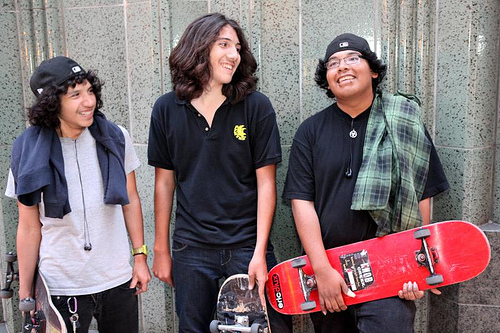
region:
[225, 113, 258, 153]
yellow logo stitched on front of shirt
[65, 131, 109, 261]
black ear buds hanging from around persons neck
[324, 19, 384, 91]
black caseball hat turned around backwards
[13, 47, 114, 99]
black caseball hat worn backwards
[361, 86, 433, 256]
gren and blue plaid shirt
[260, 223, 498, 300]
red skateboard with rubber wheels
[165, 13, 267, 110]
teenage boys with shoulder length hair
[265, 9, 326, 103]
gray and black speckled wall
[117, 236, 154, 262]
boys wide band watch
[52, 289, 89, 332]
car keys on hook attached to boys jeans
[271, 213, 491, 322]
red skateboard in his hands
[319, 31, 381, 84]
teen weaing black cap backwards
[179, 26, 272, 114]
teen with long brown hair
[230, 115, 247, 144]
yellow logo on black shirt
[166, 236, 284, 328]
dark wash denim jeans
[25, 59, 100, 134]
teen wearing cap backwards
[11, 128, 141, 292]
teen wearing white tshirt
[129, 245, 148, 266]
teen wearing yellow wrist watch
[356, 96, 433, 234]
teen with green and black shirt over shoulder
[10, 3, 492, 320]
marble wall with shiny finish behind the boys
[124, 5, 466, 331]
2 guys in black shirt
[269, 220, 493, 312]
A red skateboard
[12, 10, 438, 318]
Three boys holding skateboards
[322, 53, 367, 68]
A pair of glasses on a boy's face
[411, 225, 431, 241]
The wheel of a skateboard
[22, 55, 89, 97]
A backwards hat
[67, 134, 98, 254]
A pair of earbuds dangling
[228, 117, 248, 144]
A yellow logo on a black shirt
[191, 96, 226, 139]
An unbuttoned collar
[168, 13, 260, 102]
A boy with shoulder length hair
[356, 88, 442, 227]
A plaid shirt draped over a shoulder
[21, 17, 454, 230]
Three boys are standing.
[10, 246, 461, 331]
Boys are holding skateboard.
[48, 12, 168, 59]
Wall is grey color.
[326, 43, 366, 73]
Boy is wearing glass.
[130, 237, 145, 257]
Boy is wearing watch in left hand.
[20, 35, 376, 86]
Cap is black color.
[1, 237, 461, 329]
Wheels are black color.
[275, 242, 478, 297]
Skateboard is red color.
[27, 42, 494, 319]
Day time picture.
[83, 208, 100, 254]
Hearphone is hanging down.